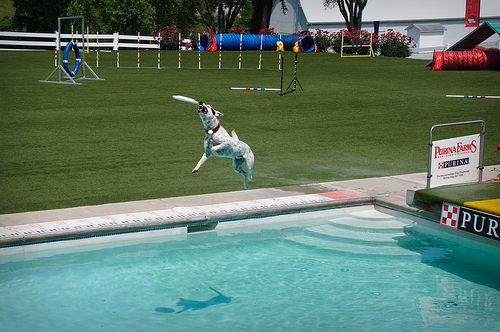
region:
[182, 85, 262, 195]
A dog is in mid air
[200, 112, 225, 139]
Dog is wearing a collar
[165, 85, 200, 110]
A flying disc in the foreground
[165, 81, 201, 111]
Flying disc is in the air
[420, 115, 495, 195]
A white sign in the foreground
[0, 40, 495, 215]
The grass is short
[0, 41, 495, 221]
Grass is covering the ground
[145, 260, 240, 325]
Dog is casting a shadow in the pool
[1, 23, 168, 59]
A white fence in the background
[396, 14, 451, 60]
White doghouse in the background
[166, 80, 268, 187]
dog catching a frisbee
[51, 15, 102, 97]
obstacle on a dog course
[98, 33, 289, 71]
obstacle on a dog course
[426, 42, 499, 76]
obstacle on a dog course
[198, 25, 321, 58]
obstacle on a dog course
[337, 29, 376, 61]
obstacle on a dog course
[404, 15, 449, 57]
obstacle on a dog course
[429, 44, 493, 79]
obstacle on a dog course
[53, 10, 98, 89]
obstacle on a dog course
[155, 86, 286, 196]
A white dog in the foreground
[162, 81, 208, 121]
A white flying disc in the foreground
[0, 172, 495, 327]
A pool in the foreground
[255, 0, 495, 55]
A white building in the background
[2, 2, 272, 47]
Tall trees in the background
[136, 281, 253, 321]
Dog's shadow is in the pool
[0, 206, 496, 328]
Pool water is light blue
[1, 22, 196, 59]
A white fence in the background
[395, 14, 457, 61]
A white doghouse in the background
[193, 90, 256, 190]
this is a dog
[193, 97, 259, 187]
this is a white dog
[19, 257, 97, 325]
this is a body of water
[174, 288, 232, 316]
this is a shadow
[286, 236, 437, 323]
this is a body of water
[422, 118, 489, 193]
this is a sign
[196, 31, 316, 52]
this is a blue tunnel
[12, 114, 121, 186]
this is green land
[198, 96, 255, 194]
a dog in the air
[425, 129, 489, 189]
a white purina hanging sign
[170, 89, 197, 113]
a wwhite frisbee in the air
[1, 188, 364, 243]
a large ruler on pool deck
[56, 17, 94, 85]
a blue dor hoop obsticle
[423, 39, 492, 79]
a red dog tunnel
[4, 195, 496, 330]
crystal clear blue pool water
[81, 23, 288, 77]
an in and out dog obsticle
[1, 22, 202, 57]
a white picket fence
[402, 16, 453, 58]
a white dog house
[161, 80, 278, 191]
white dog catching white Frisbee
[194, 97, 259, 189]
white dog catching a frisbee in the air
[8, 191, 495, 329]
large light blue pool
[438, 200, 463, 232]
red and white plaid sign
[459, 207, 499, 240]
white letters in black sign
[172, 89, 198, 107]
white frisbee in the air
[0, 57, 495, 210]
short green grass in field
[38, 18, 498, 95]
a bunch of obstacles in dog show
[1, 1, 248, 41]
green bushes in the background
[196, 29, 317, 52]
blue obstacle in the ground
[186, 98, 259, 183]
white dog with red necklace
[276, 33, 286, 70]
red and white pole in the ground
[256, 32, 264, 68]
red and white pole in the ground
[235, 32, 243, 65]
red and white pole in the ground